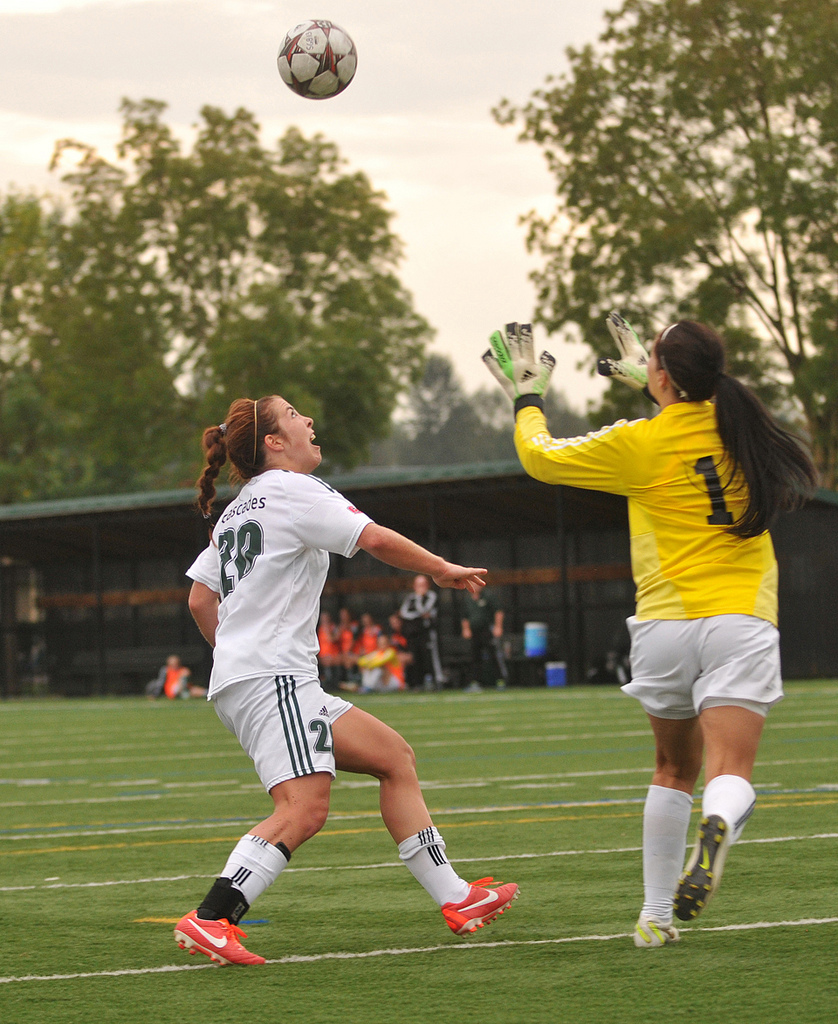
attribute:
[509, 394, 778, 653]
jersey — yellow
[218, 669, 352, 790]
shorts — white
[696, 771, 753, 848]
sock — white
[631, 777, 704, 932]
sock — white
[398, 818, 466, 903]
sock — white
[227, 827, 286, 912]
sock — white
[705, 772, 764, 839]
socks — white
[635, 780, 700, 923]
socks — white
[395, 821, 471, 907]
socks — white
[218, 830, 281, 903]
socks — white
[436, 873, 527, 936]
shoe — red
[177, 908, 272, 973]
shoe — red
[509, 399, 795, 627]
shirt — yellow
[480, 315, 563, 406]
gloves — big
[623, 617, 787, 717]
shorts — white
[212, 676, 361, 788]
shorts — white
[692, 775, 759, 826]
sock — white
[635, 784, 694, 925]
sock — white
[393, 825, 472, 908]
sock — white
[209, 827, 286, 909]
sock — white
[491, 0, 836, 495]
leaves — green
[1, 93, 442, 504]
leaves — green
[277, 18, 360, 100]
ball — white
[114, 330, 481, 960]
woman — young